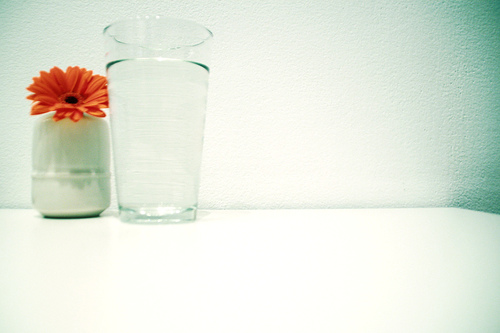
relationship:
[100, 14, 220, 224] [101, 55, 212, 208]
glass of water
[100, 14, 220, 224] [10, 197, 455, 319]
glass on table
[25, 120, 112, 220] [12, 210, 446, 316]
vase on table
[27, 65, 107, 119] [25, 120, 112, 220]
flower in vase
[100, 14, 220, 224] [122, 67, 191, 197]
glass has water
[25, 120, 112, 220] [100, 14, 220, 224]
vase shorter than glass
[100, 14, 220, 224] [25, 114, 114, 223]
glass taller than vase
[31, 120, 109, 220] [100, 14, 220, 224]
vase and glass